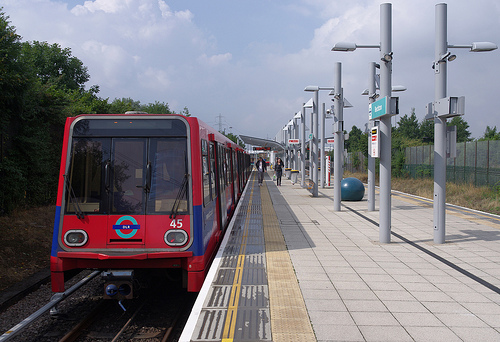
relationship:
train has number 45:
[41, 104, 257, 301] [166, 215, 186, 228]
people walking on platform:
[253, 150, 290, 191] [235, 178, 500, 341]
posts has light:
[376, 2, 401, 245] [327, 38, 383, 56]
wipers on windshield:
[63, 166, 194, 219] [64, 117, 190, 212]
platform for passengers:
[235, 178, 500, 341] [253, 150, 290, 191]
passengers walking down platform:
[253, 150, 290, 191] [235, 178, 500, 341]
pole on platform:
[332, 58, 345, 211] [235, 178, 500, 341]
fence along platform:
[403, 135, 499, 188] [235, 178, 500, 341]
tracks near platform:
[13, 282, 175, 342] [235, 178, 500, 341]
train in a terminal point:
[41, 104, 257, 301] [235, 178, 500, 341]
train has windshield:
[41, 104, 257, 301] [64, 117, 190, 212]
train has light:
[41, 104, 257, 301] [61, 227, 189, 246]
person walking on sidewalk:
[271, 156, 287, 190] [243, 176, 379, 342]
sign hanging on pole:
[363, 94, 394, 125] [376, 2, 401, 245]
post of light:
[332, 58, 345, 211] [302, 80, 333, 95]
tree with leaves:
[1, 14, 40, 198] [3, 7, 33, 125]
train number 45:
[41, 104, 257, 301] [166, 215, 186, 228]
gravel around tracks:
[20, 298, 174, 333] [13, 282, 175, 342]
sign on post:
[367, 123, 382, 162] [376, 2, 401, 245]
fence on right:
[403, 135, 499, 188] [453, 5, 499, 309]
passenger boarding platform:
[253, 150, 290, 191] [235, 178, 500, 341]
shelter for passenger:
[239, 133, 287, 153] [253, 150, 290, 191]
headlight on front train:
[61, 227, 189, 246] [41, 104, 257, 301]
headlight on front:
[61, 227, 189, 246] [48, 109, 204, 291]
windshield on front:
[64, 117, 190, 212] [48, 109, 204, 291]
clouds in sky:
[40, 4, 496, 88] [66, 0, 357, 58]